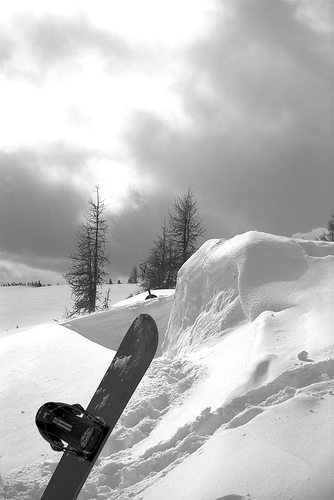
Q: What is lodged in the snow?
A: A snowboard.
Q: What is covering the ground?
A: Snow.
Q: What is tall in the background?
A: Trees.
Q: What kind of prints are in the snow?
A: Footprints.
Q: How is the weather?
A: Dark and cloudy.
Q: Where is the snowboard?
A: In the snow.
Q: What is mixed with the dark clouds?
A: White clouds.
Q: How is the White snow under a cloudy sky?
A: In piles.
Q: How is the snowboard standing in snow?
A: On a slant.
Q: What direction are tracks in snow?
A: To the left.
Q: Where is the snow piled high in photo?
A: Front of snowboard.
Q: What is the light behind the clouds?
A: The sun.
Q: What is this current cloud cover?
A: Mostly cloudy.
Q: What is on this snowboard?
A: A boot holder.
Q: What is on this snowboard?
A: A boot binding.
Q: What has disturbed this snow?
A: Footprints.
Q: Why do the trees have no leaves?
A: This is winter.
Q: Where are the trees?
A: Behind the snow drift.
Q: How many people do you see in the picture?
A: None.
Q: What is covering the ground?
A: Snow.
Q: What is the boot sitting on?
A: A ski.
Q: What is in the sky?
A: Clouds.